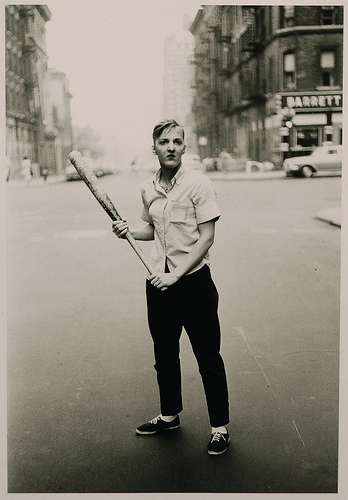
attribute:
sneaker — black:
[206, 429, 228, 455]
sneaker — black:
[134, 414, 180, 434]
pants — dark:
[126, 261, 274, 394]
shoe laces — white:
[148, 414, 225, 443]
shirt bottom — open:
[149, 253, 182, 284]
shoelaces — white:
[213, 429, 220, 445]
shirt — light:
[129, 164, 229, 280]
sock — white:
[159, 413, 179, 421]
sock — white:
[211, 425, 227, 433]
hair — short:
[126, 101, 186, 146]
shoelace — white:
[143, 408, 175, 443]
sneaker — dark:
[120, 392, 176, 441]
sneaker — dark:
[195, 428, 245, 469]